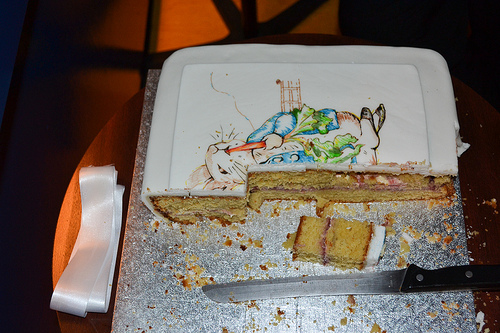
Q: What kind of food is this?
A: Cake.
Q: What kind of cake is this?
A: Two layer yellow cake.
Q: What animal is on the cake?
A: Rabbit with carrot.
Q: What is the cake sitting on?
A: Foil covered board.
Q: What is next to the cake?
A: Knife with black blade.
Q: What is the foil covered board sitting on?
A: Table.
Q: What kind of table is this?
A: Wooden table.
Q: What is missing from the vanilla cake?
A: Pieces.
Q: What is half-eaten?
A: A party cake.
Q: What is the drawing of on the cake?
A: A rabbit.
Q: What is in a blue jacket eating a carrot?
A: A rabbit,.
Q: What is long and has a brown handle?
A: A knife.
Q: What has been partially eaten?
A: A cake.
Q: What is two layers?
A: A cake.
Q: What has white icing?
A: A cake.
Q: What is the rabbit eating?
A: A carrot.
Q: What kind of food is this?
A: Cake.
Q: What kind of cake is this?
A: Rabbit on top of cake.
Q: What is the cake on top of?
A: Silve rfoil.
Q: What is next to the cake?
A: Silver knife with black handle.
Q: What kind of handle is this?
A: Black handle.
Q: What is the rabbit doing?
A: Eating rabbit.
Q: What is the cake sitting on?
A: Table.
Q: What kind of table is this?
A: Wooden table.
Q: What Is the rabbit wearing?
A: Blue coat.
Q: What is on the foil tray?
A: A cake and a knife.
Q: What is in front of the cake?
A: A long knife.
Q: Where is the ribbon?
A: On the table by the cake.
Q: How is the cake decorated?
A: A picture of a rabbit on white icing.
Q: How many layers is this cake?
A: Two.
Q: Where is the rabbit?
A: On the cake.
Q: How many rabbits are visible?
A: One.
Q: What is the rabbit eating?
A: A carrot.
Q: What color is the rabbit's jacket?
A: Blue.